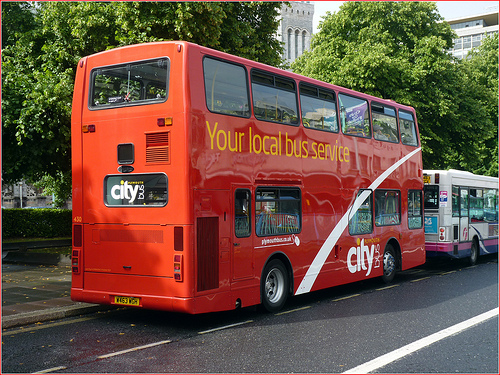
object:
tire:
[254, 255, 294, 314]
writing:
[207, 119, 349, 163]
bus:
[71, 41, 423, 317]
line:
[336, 306, 499, 374]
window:
[201, 52, 416, 149]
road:
[0, 255, 499, 375]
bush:
[0, 122, 73, 240]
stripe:
[263, 144, 427, 297]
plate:
[109, 295, 140, 310]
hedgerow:
[442, 11, 484, 31]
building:
[271, 0, 319, 76]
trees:
[450, 28, 500, 176]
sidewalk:
[0, 239, 416, 327]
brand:
[344, 231, 382, 280]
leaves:
[24, 97, 63, 140]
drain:
[7, 267, 54, 283]